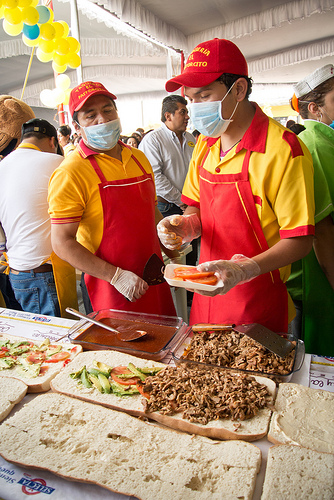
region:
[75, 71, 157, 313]
man wearing a red had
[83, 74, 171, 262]
man wearing a yellow and red shirt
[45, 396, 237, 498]
large bread on table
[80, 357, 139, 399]
guacamole on bread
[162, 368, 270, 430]
meat on bread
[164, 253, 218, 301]
tomatoes in a tray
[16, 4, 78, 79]
baloons on a stick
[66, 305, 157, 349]
spoon in a baking dish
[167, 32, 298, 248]
man weaing a blue mask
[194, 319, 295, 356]
spatula on top of meat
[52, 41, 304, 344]
two guys with red and yellow uniform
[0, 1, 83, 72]
yellow and light blue balloons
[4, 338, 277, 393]
food in bread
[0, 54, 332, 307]
lot of people behind two guys in red and yellow uniform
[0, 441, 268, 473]
on ebig bread with no food on it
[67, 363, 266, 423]
one big bread with a lot of food on it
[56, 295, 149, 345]
big grey spoon in the sauce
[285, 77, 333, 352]
one men in green t-shirt in the right side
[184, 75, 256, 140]
light blue mouth cap in guy in the right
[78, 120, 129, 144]
light blue mouth cap in guy in the left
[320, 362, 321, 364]
top of a table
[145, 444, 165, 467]
part of a bread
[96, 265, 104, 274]
arm of a man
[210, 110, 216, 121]
part of a glove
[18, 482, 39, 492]
edge of a table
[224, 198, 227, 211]
part of a cloth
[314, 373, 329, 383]
face of a man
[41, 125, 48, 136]
back of a man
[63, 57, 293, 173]
men wearing white masks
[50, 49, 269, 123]
men wearing red hats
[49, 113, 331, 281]
men wearing yellow shirts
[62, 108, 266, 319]
men wearing red aprons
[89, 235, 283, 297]
men wearing latex gloves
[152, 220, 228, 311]
man holding tray of tomatoes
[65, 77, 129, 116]
yellow lettering on hat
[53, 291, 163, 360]
the spoon is in dish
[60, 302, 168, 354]
the spoon is silver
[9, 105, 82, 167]
man wearing black hat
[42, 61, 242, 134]
two people wearing white masks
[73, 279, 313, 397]
two glass dishes with food in them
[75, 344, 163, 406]
vegetables on bread in photo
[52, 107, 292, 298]
two men wearing red aprons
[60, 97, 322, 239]
two men wearing yellow shirts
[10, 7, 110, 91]
yellow and blue balloons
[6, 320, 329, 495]
several pieces of large bread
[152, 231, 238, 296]
white dish with tomatoes in it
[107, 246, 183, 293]
man holding a spatula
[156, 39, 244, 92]
red hat with yellow lettering